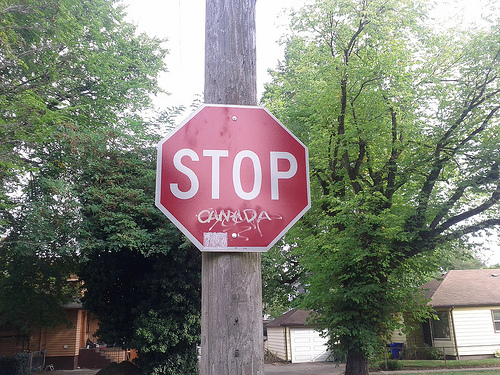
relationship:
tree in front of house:
[262, 6, 499, 374] [267, 264, 499, 359]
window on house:
[488, 300, 499, 340] [380, 269, 498, 361]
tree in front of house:
[262, 6, 499, 374] [421, 260, 493, 355]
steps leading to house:
[78, 347, 125, 367] [0, 258, 136, 371]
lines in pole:
[229, 311, 258, 361] [203, 0, 255, 105]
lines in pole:
[229, 311, 258, 361] [200, 251, 262, 373]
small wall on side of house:
[72, 340, 136, 366] [393, 271, 492, 369]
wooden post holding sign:
[189, 8, 280, 362] [151, 102, 311, 259]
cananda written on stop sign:
[194, 205, 272, 227] [145, 97, 316, 260]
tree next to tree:
[0, 0, 159, 372] [0, 88, 307, 373]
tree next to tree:
[262, 6, 499, 374] [28, 38, 160, 346]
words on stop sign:
[194, 205, 283, 233] [154, 101, 312, 252]